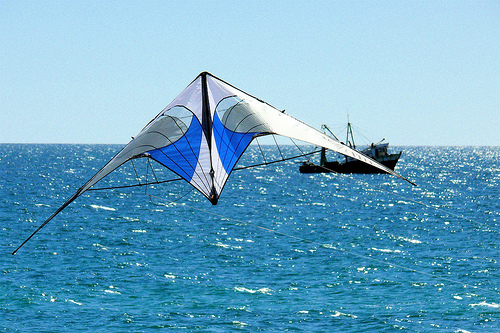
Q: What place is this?
A: It is an ocean.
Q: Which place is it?
A: It is an ocean.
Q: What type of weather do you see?
A: It is cloudless.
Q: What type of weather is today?
A: It is cloudless.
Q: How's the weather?
A: It is cloudless.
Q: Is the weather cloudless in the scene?
A: Yes, it is cloudless.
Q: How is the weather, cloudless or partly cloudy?
A: It is cloudless.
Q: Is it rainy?
A: No, it is cloudless.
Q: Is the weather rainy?
A: No, it is cloudless.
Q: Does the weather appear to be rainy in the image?
A: No, it is cloudless.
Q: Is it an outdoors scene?
A: Yes, it is outdoors.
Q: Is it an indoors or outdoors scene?
A: It is outdoors.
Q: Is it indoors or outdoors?
A: It is outdoors.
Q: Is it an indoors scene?
A: No, it is outdoors.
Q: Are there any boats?
A: Yes, there is a boat.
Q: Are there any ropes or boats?
A: Yes, there is a boat.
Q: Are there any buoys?
A: No, there are no buoys.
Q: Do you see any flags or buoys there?
A: No, there are no buoys or flags.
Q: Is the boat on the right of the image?
A: Yes, the boat is on the right of the image.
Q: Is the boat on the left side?
A: No, the boat is on the right of the image.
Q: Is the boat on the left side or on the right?
A: The boat is on the right of the image.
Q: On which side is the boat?
A: The boat is on the right of the image.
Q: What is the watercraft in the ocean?
A: The watercraft is a boat.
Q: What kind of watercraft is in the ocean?
A: The watercraft is a boat.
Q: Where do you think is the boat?
A: The boat is in the ocean.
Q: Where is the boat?
A: The boat is in the ocean.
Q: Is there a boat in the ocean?
A: Yes, there is a boat in the ocean.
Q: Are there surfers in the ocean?
A: No, there is a boat in the ocean.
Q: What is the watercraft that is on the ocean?
A: The watercraft is a boat.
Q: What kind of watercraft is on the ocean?
A: The watercraft is a boat.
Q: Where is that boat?
A: The boat is on the ocean.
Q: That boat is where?
A: The boat is on the ocean.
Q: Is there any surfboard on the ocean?
A: No, there is a boat on the ocean.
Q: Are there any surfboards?
A: No, there are no surfboards.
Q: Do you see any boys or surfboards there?
A: No, there are no surfboards or boys.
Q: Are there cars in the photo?
A: No, there are no cars.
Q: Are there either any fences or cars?
A: No, there are no cars or fences.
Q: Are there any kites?
A: Yes, there is a kite.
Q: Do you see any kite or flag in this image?
A: Yes, there is a kite.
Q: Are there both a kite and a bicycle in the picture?
A: No, there is a kite but no bicycles.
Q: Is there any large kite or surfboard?
A: Yes, there is a large kite.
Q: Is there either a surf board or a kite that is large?
A: Yes, the kite is large.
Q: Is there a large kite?
A: Yes, there is a large kite.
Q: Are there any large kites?
A: Yes, there is a large kite.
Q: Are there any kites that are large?
A: Yes, there is a kite that is large.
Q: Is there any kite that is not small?
A: Yes, there is a large kite.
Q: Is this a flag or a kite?
A: This is a kite.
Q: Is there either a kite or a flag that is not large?
A: No, there is a kite but it is large.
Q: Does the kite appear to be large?
A: Yes, the kite is large.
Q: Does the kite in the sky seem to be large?
A: Yes, the kite is large.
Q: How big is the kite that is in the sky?
A: The kite is large.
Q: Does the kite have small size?
A: No, the kite is large.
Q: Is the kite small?
A: No, the kite is large.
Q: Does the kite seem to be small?
A: No, the kite is large.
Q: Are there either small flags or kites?
A: No, there is a kite but it is large.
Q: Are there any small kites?
A: No, there is a kite but it is large.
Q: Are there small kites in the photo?
A: No, there is a kite but it is large.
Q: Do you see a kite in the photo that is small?
A: No, there is a kite but it is large.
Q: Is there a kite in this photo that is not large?
A: No, there is a kite but it is large.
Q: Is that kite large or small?
A: The kite is large.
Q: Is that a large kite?
A: Yes, that is a large kite.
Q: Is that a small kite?
A: No, that is a large kite.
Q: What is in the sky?
A: The kite is in the sky.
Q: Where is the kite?
A: The kite is in the sky.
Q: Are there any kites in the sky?
A: Yes, there is a kite in the sky.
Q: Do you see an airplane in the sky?
A: No, there is a kite in the sky.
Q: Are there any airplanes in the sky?
A: No, there is a kite in the sky.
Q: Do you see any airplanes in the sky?
A: No, there is a kite in the sky.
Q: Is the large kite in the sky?
A: Yes, the kite is in the sky.